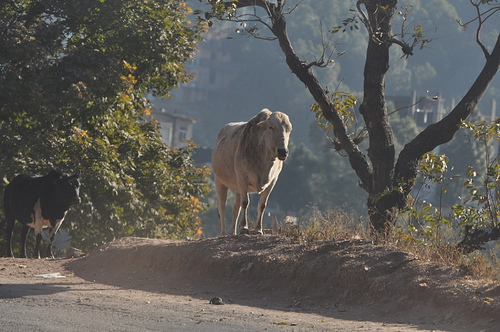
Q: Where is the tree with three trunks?
A: By the white cow.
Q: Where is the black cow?
A: Behind the white cow.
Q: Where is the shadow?
A: In the dirt.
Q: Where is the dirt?
A: On the ground.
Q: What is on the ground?
A: Dirt.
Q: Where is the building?
A: Behind the green trees.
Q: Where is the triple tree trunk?
A: By the white animal.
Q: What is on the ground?
A: Dirt.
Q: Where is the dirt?
A: On the ground.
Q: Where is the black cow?
A: Behind the white cow.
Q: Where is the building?
A: Far behind the cows.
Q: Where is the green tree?
A: Behind the black cow.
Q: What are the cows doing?
A: Standing.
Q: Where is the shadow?
A: In the dirt.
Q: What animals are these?
A: Cows.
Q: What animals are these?
A: Cows.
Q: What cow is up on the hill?
A: The white one.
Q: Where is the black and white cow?
A: Near the leafy tree.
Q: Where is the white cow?
A: On a small hill.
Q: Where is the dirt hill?
A: On the side of the road.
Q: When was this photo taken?
A: During the day.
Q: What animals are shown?
A: Cattle.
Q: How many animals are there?
A: Two.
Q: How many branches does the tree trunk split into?
A: Three.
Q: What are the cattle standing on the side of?
A: A dirt road.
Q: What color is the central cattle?
A: White.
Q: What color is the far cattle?
A: Black.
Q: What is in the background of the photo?
A: Houses.